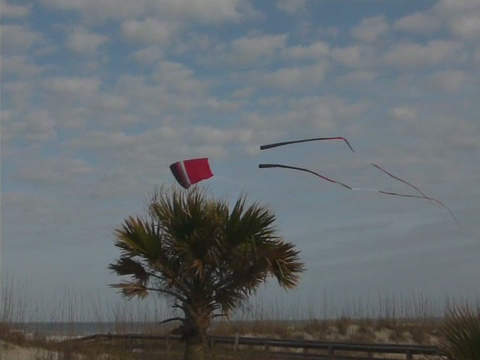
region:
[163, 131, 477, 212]
Kite blowing in the wind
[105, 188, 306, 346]
Small shrub or bush.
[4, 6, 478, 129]
Cloudy day with no visible rain.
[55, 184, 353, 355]
Small shrub/bush grows amongst weeds in sandy ground cover.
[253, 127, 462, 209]
Kite has long black tail, flying in the wind.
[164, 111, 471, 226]
The kite has 3 colors (black, white, red), and is rectangular.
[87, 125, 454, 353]
The kite may be caught in the shrub, or just flying over it.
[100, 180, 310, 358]
The tree or shrub has green fronds and a brown trunk.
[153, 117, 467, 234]
The kite is aloft but there is no flyer in the picture.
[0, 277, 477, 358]
Short grasses or weeds grow all around the bush/tree.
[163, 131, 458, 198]
A kite in the air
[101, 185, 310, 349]
A single palm tree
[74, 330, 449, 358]
A metal guard rail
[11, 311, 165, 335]
The ocean shoreline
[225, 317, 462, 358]
Sand covered dune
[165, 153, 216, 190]
The body part of a kite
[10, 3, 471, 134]
A cloudy sky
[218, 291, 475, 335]
Grass growing on a dune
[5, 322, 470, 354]
Sandy ground with grass growing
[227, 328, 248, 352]
A wooden guardrail post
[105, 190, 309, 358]
Palm Tree in the beach.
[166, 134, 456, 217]
Kite flying in the sky.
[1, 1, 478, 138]
Clouds in the sky.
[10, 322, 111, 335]
Ocean water at the beach.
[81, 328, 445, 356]
Railing of the walkway to the beach.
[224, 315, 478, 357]
Grass on sandunes at the beach.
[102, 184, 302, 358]
Palm tree at the beach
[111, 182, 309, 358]
Palm tree at the beach.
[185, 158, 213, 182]
Red stripe on a kite.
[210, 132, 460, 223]
Tails of a kite at the beach.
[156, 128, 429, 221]
a kite flying through the air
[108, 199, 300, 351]
a plam tree growing on the beach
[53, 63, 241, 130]
cloudy blue skies over the beach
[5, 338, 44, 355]
tan sand of the beach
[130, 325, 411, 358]
a guard rail next to the beach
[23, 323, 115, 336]
calm waters of the ocean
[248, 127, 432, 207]
black and red tail of the kite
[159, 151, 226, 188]
black and red body of the kite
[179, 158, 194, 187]
white stripe on the kite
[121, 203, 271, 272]
blooming leaves of the palm tree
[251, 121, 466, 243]
two streamers on the kite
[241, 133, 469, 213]
streamers are black, white and red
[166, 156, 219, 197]
kite has a white stripe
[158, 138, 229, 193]
kite is black, white and red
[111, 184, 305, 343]
palm tree below the kite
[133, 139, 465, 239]
kite is flying in the sky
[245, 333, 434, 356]
pathway over the dune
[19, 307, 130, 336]
ocean on the other side of dune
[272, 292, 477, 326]
grass growing on the dune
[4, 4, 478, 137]
small white puffy clouds in the sky